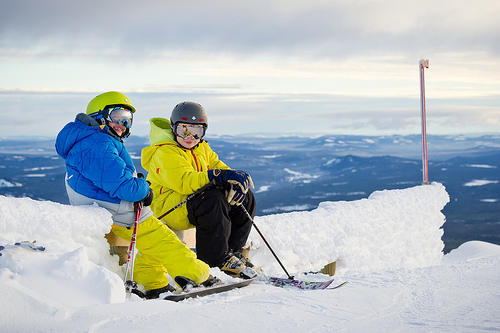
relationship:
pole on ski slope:
[417, 53, 433, 186] [1, 155, 497, 330]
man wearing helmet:
[48, 84, 224, 292] [87, 90, 138, 113]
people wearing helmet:
[140, 101, 259, 280] [169, 100, 209, 130]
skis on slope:
[165, 227, 353, 329] [1, 180, 496, 330]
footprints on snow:
[381, 270, 412, 310] [63, 287, 160, 324]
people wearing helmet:
[140, 101, 259, 280] [171, 100, 213, 138]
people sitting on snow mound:
[140, 101, 259, 280] [0, 180, 499, 333]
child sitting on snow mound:
[55, 91, 227, 300] [0, 180, 499, 333]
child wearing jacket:
[55, 91, 227, 300] [54, 118, 158, 217]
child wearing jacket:
[55, 91, 227, 300] [51, 117, 152, 204]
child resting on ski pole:
[55, 91, 227, 300] [119, 194, 145, 292]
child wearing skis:
[55, 91, 227, 300] [163, 277, 254, 302]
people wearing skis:
[140, 101, 259, 280] [242, 268, 351, 290]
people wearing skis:
[140, 101, 259, 280] [300, 258, 341, 276]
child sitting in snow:
[55, 91, 227, 300] [2, 182, 498, 331]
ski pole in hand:
[233, 194, 308, 288] [226, 182, 248, 207]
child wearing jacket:
[55, 91, 227, 300] [54, 111, 152, 226]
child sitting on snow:
[55, 92, 227, 299] [2, 182, 498, 331]